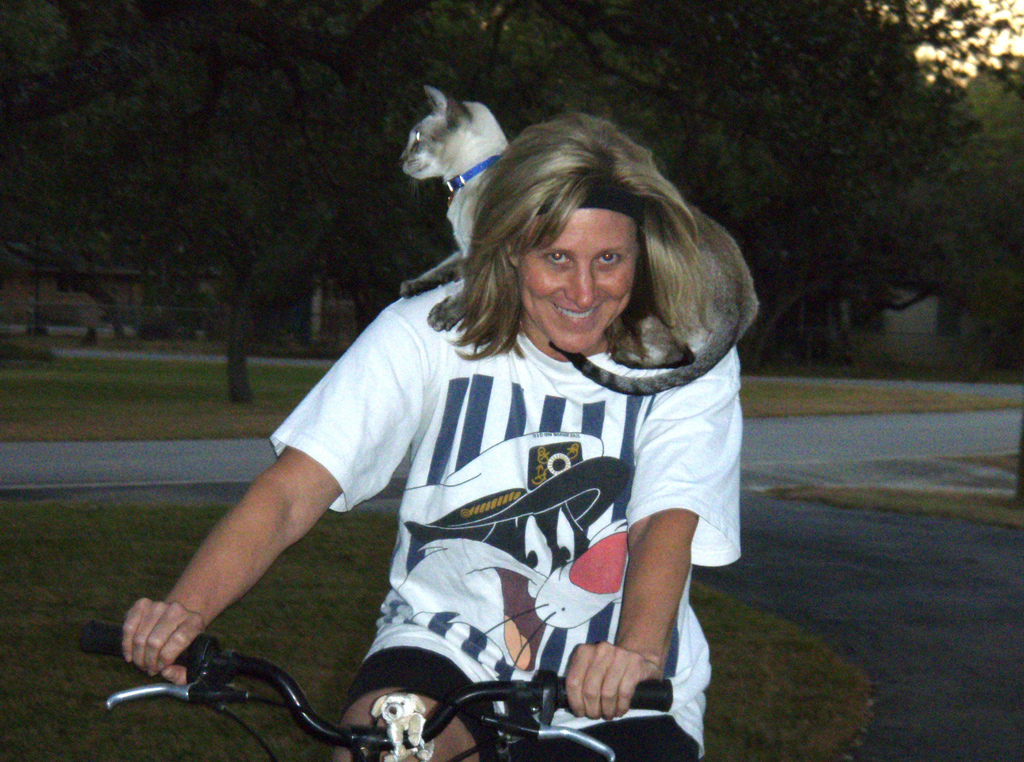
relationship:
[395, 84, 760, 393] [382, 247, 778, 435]
cat on girl's shoulders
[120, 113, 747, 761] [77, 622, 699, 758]
lady sitting on a bike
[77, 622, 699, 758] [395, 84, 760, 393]
bike has a cat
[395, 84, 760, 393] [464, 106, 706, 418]
cat around her head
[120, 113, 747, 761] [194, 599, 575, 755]
lady riding her bike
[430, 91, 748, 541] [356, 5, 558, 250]
lady with cat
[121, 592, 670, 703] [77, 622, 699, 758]
hands holding bike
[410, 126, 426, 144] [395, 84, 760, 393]
eye belonging to cat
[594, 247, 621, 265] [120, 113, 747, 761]
eye belonging to lady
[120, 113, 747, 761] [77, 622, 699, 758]
lady riding bike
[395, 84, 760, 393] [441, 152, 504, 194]
cat wearing collar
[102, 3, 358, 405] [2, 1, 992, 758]
tree standing in city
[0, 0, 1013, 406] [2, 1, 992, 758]
tree standing in city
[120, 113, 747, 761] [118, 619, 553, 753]
lady riding a bike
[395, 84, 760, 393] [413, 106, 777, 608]
cat on woman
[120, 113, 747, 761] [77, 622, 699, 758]
lady on bike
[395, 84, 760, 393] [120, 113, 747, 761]
cat on lady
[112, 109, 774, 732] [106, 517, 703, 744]
lady on bike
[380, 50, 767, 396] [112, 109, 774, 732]
cat on lady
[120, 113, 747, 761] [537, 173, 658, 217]
lady with a black headband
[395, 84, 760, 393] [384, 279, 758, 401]
cat on shoulder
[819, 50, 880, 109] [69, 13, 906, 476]
leaves on tree